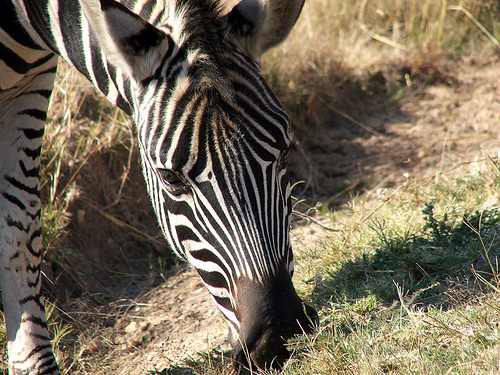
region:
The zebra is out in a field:
[10, 12, 470, 367]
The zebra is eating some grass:
[35, 6, 390, 371]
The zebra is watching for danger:
[40, 20, 450, 350]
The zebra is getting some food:
[30, 25, 466, 350]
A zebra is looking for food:
[37, 14, 448, 371]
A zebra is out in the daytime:
[10, 5, 470, 365]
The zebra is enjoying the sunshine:
[22, 10, 467, 355]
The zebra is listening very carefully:
[15, 3, 478, 363]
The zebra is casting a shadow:
[23, 10, 483, 355]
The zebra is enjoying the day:
[23, 12, 485, 339]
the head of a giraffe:
[12, 9, 435, 365]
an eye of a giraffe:
[136, 148, 191, 212]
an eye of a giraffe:
[271, 99, 312, 192]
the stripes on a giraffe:
[194, 189, 252, 286]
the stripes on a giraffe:
[207, 120, 256, 206]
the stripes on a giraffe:
[134, 79, 198, 147]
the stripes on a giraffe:
[50, 5, 123, 100]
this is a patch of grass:
[340, 248, 403, 346]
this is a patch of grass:
[386, 215, 458, 292]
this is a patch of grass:
[305, 305, 367, 365]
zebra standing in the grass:
[37, 68, 336, 346]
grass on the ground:
[335, 202, 459, 374]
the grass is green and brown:
[334, 175, 470, 357]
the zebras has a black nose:
[214, 267, 344, 369]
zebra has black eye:
[146, 161, 196, 206]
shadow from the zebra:
[329, 191, 493, 323]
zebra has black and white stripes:
[64, 6, 299, 373]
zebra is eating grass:
[16, 2, 352, 369]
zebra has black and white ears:
[82, 4, 187, 81]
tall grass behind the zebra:
[326, 2, 494, 115]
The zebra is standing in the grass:
[0, 11, 495, 356]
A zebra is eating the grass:
[5, 0, 495, 340]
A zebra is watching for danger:
[5, 10, 485, 350]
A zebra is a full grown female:
[20, 10, 460, 370]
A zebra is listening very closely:
[15, 5, 495, 365]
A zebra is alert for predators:
[16, 0, 486, 361]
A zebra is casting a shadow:
[26, 11, 471, 356]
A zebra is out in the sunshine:
[26, 12, 491, 352]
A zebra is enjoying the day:
[23, 7, 486, 354]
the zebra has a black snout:
[232, 263, 323, 374]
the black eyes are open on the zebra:
[144, 135, 301, 199]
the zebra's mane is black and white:
[163, 0, 233, 77]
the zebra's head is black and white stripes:
[131, 55, 296, 279]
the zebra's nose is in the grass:
[130, 149, 382, 365]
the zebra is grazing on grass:
[148, 123, 328, 371]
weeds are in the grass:
[369, 191, 496, 281]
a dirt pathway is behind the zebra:
[39, 5, 499, 334]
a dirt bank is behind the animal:
[34, 55, 434, 301]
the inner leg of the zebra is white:
[4, 74, 36, 360]